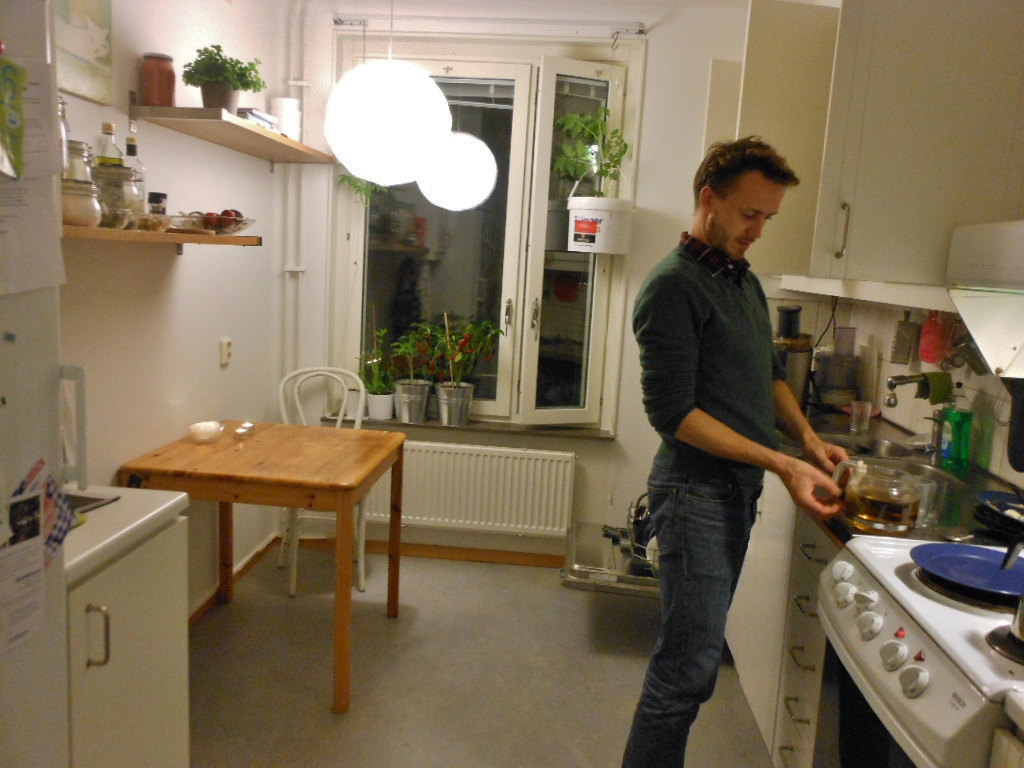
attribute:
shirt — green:
[628, 234, 780, 468]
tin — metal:
[437, 379, 476, 431]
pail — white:
[568, 193, 636, 258]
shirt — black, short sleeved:
[630, 230, 790, 483]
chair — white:
[277, 366, 376, 597]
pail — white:
[565, 164, 630, 260]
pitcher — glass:
[843, 458, 933, 532]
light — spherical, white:
[324, 56, 452, 187]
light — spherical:
[419, 130, 499, 210]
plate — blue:
[911, 538, 1022, 597]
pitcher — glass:
[835, 448, 928, 534]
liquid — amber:
[849, 486, 922, 529]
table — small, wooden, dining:
[115, 418, 406, 716]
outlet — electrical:
[214, 335, 238, 368]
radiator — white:
[302, 430, 578, 547]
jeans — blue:
[625, 439, 769, 760]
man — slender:
[624, 123, 849, 762]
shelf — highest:
[138, 95, 332, 165]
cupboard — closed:
[74, 513, 195, 766]